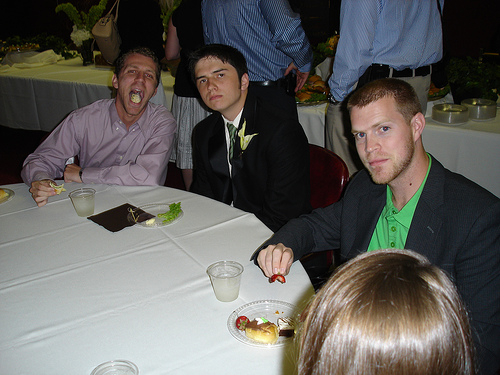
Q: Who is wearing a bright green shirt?
A: The man closest to the camera.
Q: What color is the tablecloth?
A: White.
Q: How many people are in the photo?
A: Eight.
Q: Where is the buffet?
A: Behind the table where people are sitting.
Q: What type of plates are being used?
A: Plastic.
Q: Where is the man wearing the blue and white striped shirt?
A: Standing at the buffet table.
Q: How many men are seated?
A: Three.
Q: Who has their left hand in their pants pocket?
A: The man at the buffet table who is wearing a solid blue shirt.